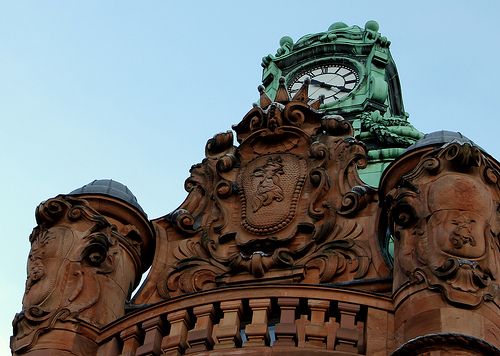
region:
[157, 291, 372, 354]
aged columns on a belcony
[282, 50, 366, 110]
clock with roman numerals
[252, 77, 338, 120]
stone scalped crown on top of a building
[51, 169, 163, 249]
dome top on top of a stone structure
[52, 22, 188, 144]
clear blue day light sky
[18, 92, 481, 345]
old ancient detailed building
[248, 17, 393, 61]
green aged sculpted structure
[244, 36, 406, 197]
green structure on top of a brown structure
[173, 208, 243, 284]
carved detailed stone design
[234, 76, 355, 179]
pointy crown on top of building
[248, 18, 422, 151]
there is a clock tower on top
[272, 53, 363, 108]
Clock face is white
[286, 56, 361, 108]
Numerals are roman and black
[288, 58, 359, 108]
clock hands are black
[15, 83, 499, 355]
The building has ornate stonework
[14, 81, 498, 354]
the lower section is bronze colored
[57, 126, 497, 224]
black domes sit on top of corner posts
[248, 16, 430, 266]
clock tower section is colored petina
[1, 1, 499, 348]
The sky is clear and blue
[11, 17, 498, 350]
building stonework is renaissance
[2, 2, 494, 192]
The sky is blue.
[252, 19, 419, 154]
Clock tower is green.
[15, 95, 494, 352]
The building is brown.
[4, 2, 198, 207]
No clouds in sky.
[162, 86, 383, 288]
Sculptures on building.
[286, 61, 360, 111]
The clock face is white.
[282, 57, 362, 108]
Clock hands are black.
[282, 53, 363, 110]
Numbers are roman numeral.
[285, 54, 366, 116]
The clock says 4:20.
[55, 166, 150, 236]
The roof is black.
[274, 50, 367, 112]
clock face on a green clock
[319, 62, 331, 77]
roman numeral of twelve on a clock face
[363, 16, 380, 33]
green ball on top of a clock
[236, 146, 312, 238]
decorative crest on a balcony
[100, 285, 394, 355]
columns on a red balcony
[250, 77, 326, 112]
red crown in front of a green clock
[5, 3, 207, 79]
cloudless blue sky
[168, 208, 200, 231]
curl of red on a balcony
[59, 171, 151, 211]
top of a red column on a balcony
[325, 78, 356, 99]
minute hand at twenty on a clock face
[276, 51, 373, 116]
a large metal clock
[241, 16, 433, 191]
a green clock tower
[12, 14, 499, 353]
an old victorian building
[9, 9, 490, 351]
an old building with clock tower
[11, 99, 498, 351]
fancy brown architecture with clock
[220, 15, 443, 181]
a weather clock tower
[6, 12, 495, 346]
an old victorian clock tower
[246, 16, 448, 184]
a fancy green clock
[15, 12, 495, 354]
a large brown and green building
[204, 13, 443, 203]
large green clock on a building